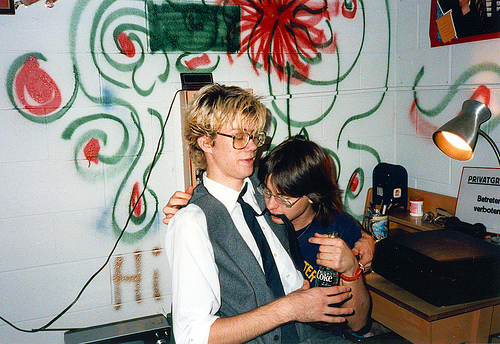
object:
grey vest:
[184, 179, 357, 344]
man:
[157, 82, 376, 344]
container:
[371, 162, 408, 216]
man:
[161, 133, 401, 343]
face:
[214, 114, 264, 181]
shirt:
[291, 205, 375, 338]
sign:
[452, 165, 500, 236]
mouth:
[270, 211, 282, 220]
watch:
[338, 263, 363, 283]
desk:
[359, 210, 500, 343]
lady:
[163, 134, 383, 344]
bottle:
[311, 231, 341, 331]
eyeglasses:
[255, 187, 302, 208]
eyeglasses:
[210, 124, 268, 152]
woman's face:
[262, 180, 309, 225]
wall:
[1, 0, 499, 344]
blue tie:
[235, 180, 303, 343]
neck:
[198, 166, 251, 203]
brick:
[45, 158, 108, 218]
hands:
[293, 230, 354, 324]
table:
[359, 182, 499, 343]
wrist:
[340, 266, 364, 286]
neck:
[202, 163, 255, 191]